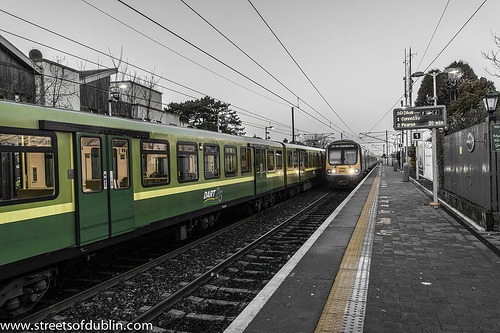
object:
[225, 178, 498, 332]
walkway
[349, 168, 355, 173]
headlight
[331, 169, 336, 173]
headlight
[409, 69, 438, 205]
pole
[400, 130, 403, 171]
pole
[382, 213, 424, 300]
ground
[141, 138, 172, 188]
window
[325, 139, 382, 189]
train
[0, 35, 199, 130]
buildings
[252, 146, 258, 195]
train door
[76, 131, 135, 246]
doors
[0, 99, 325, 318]
train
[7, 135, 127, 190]
lights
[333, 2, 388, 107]
gray sky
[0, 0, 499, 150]
electric lines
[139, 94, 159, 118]
wall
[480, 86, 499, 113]
streetlight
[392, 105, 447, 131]
post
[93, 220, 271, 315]
gravel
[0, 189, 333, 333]
tracks